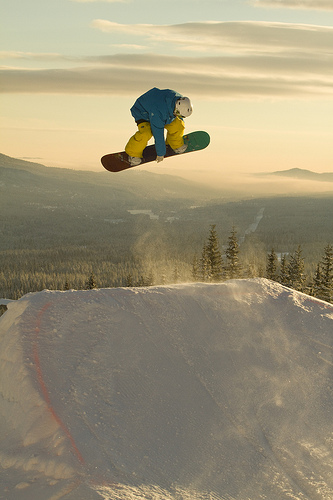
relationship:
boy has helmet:
[125, 87, 194, 166] [176, 92, 192, 116]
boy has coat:
[125, 87, 194, 166] [135, 87, 168, 120]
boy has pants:
[125, 87, 194, 166] [133, 120, 182, 161]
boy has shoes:
[125, 87, 194, 166] [129, 142, 188, 165]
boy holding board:
[125, 87, 194, 166] [99, 127, 216, 169]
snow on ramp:
[0, 276, 333, 500] [26, 273, 308, 469]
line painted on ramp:
[27, 297, 82, 491] [11, 276, 318, 490]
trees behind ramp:
[185, 220, 328, 321] [11, 276, 318, 490]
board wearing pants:
[101, 130, 211, 172] [124, 122, 189, 158]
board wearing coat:
[101, 130, 211, 172] [129, 88, 182, 156]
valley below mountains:
[6, 225, 323, 300] [13, 144, 322, 236]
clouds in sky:
[104, 13, 311, 76] [6, 4, 320, 98]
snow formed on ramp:
[13, 283, 327, 496] [11, 276, 318, 490]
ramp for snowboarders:
[11, 276, 318, 490] [87, 75, 220, 185]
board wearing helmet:
[101, 130, 211, 172] [168, 84, 198, 121]